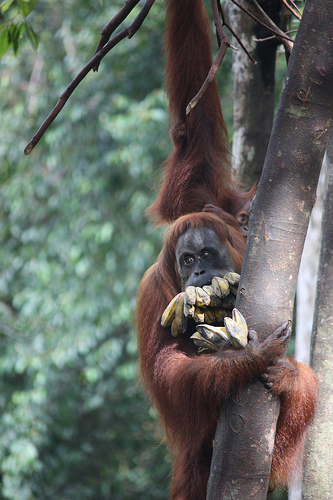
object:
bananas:
[161, 290, 186, 329]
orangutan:
[134, 202, 320, 500]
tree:
[204, 0, 333, 500]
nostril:
[194, 271, 199, 277]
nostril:
[199, 269, 206, 275]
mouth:
[191, 281, 212, 290]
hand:
[245, 320, 303, 366]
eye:
[201, 249, 213, 261]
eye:
[182, 255, 195, 267]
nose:
[193, 260, 206, 277]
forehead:
[176, 225, 218, 252]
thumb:
[247, 329, 258, 344]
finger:
[275, 318, 291, 338]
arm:
[157, 331, 281, 404]